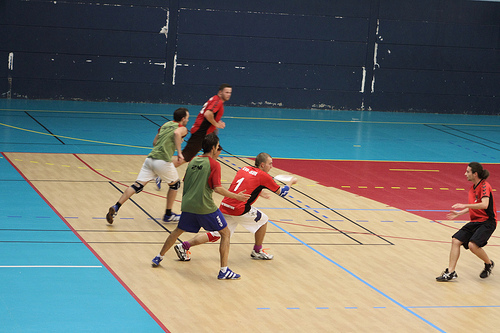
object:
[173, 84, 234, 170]
man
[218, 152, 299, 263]
man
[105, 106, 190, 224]
man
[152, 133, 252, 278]
man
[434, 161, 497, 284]
man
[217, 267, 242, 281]
shoe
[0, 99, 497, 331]
floor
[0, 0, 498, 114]
wall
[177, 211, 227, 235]
shorts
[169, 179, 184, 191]
pad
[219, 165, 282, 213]
jersey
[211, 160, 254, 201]
arm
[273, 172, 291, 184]
frisbee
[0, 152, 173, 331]
line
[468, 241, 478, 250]
knee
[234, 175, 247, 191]
number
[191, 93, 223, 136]
jersey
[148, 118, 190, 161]
shirt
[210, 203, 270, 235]
shorts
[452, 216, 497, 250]
shorts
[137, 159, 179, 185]
shorts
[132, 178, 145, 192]
pad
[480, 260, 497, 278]
shoe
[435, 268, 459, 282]
shoe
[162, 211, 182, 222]
shoe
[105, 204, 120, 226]
shoe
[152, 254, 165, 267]
shoe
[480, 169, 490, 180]
ponytail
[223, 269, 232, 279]
stripe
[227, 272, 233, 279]
stripe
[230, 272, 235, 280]
stripe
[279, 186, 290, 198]
pad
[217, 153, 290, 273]
man